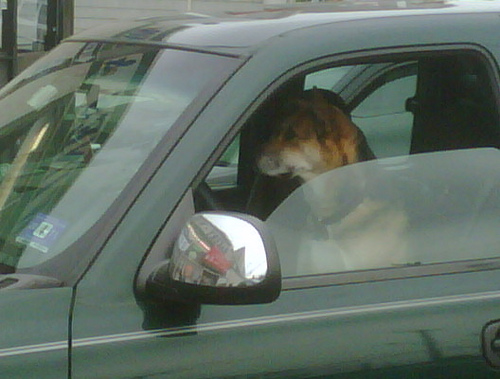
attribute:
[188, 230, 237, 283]
reflection — power lines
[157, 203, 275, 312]
mirror — black, silver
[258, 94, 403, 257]
dog — white, brown, looking, content, waiting, sitting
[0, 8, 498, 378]
car — green, parked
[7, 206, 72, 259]
sticker — white, blue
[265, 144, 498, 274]
window — down, open, halfway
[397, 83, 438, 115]
seat buckle — seat belt, strap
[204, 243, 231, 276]
awning — red